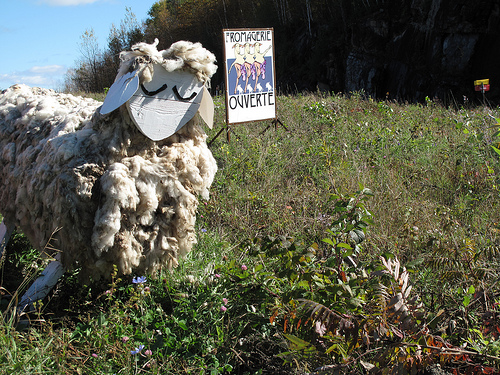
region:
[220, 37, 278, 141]
blue and white sign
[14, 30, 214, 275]
faux sheep on grass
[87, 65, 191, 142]
sheep has white face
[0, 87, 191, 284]
sheep has thick white fur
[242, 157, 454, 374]
small green bush in grass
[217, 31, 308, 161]
black letters on sign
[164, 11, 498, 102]
thick and dark green trees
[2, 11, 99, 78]
blue and white sky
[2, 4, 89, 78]
small white clouds in sky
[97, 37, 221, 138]
white ears placed on sheep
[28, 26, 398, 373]
this is a fake sheep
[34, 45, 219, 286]
the fake sheep has wool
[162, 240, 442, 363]
these are bushes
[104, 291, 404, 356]
there are wildflowers here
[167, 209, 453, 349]
the bushes are green and brown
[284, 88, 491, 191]
there are weeds here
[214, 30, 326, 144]
this is a sign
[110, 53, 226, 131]
the sheep's eyes are closed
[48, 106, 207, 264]
the wool is gray and white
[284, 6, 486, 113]
this is a forest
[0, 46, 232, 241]
a scarecrow on the grass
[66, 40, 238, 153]
its face is made from boxes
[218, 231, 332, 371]
the grass has flowers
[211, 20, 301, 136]
a white signboard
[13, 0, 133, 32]
the sky is blue in colour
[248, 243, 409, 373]
leaves are on the floor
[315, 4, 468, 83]
the trees are green in colour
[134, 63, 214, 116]
the box has some paintings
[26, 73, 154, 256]
the body is covered by wool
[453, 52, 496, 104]
a red and yellow signboard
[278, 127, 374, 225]
assortment of green vegetation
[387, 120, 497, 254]
assortment of green vegetation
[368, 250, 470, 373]
assortment of green vegetation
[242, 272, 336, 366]
assortment of green vegetation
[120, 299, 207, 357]
assortment of green vegetation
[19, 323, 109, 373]
assortment of green vegetation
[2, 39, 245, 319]
fake lamb on ground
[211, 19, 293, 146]
white sign posted next to fake lamb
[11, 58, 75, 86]
clouds in the sky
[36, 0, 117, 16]
cloud in the sky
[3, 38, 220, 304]
fake sheep statue made from cardboard and wool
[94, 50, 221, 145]
white cardboard sheep face with black eyes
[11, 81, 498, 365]
green grassy field with sign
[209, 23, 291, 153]
blue and white sign advertising cheese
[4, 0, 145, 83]
clear bright blue sky with few clouds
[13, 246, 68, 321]
white wooden legas of sheep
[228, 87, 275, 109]
sign reads open in French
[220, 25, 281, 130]
sign reads Ouverte in French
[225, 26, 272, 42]
fromagerie written on top of sign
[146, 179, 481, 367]
bushy grassy weed growth in foreground